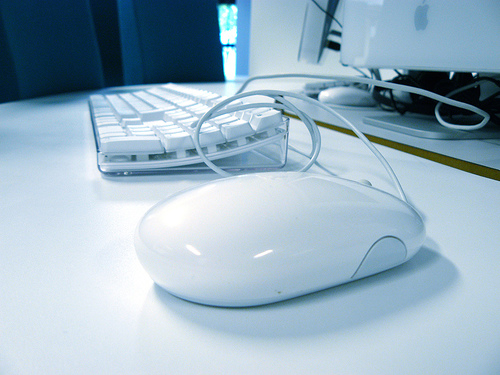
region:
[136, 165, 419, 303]
White computer mouse.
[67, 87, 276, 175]
White computer keyboard.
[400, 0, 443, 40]
Apple icon on the computer.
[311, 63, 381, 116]
Another mouse and keyboard.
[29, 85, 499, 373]
Large white table for computers to rest upon.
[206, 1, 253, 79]
The outdoors.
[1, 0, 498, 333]
A large room with computers.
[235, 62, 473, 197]
A white cord connecting the mouse to computer.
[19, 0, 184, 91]
A wall in the room.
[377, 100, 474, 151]
Computer monitor stand.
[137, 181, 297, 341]
the mouse is white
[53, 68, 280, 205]
the keyboard is white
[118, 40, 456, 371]
two computer mouses are present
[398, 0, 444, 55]
apple logo on computer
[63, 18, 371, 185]
two keyboards on desk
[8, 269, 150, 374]
the desk is white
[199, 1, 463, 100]
two computer monitors on desk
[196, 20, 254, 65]
window in the background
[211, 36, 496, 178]
wires for computers are present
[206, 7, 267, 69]
trees seen out of window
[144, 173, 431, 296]
a white computer mouse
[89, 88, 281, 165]
a white computer keyboard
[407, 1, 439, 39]
a company logo on a computer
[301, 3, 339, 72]
a computer monitor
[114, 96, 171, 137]
keys on a keyboard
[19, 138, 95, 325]
a white colored top of a desk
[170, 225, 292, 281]
light reflection on a mouse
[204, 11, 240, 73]
a window in a room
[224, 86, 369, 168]
a cord for an electronic device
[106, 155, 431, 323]
a mouse on a flat surface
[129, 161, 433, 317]
white computer mouse on desk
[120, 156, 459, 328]
computer mouse casting a shadow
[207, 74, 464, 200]
cable connecting mouse to keyboard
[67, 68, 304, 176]
macintosh computer keyboard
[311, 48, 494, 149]
base of computer monitor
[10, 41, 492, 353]
white desk top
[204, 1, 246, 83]
window to outside behind the desk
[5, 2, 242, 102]
grey wall behind the desk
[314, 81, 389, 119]
computer mouse in the background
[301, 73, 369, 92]
computer keyboard in the background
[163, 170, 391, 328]
the mouse is white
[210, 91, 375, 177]
the cords lead to computer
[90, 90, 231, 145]
there is a keyboard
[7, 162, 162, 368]
the table is white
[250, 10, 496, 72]
there a two moniters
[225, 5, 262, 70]
the window has light coming thru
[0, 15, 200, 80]
the wall is dark in color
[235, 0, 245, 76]
door frame is blue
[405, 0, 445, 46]
moniter has the apple logo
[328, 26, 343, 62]
cords are black on the computer